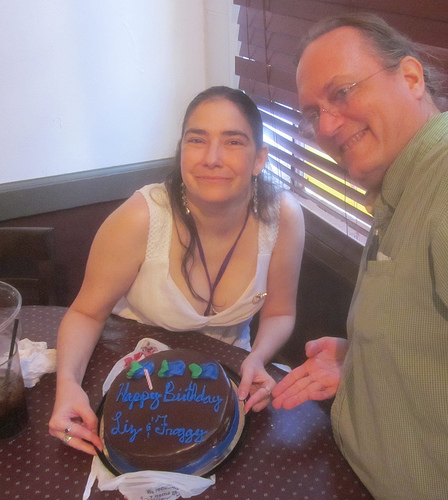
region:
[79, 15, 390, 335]
a mom and dad giving a birthday cake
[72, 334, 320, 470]
a brown and blue birthday cake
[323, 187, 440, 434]
the man has on a green shirt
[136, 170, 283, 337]
this lady is wearing a white shirt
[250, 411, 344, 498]
a brown table cloth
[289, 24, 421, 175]
this man is wearing glasses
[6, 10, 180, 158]
this wall in the house is white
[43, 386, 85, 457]
rings on the woman's fingers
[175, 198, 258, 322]
a badge string around the lady's neck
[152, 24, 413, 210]
the couple is happy about the cake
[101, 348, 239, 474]
a chocolate birthday cake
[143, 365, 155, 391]
one white birthday candle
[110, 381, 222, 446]
writing with blue frosting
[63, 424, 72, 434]
a ring on her right finger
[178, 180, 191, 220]
long gold color earing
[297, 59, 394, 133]
wire rim eye glasses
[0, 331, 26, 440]
a clear glass of soda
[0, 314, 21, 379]
a plastic drink stirrer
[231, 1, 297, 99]
brown horizontal blinds on the window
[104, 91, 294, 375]
this is a lady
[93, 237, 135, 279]
the lady is light skinned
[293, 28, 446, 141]
this is a man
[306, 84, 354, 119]
this is a spectacle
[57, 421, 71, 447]
this is a ring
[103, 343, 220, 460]
this is a cake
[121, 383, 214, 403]
this is a writing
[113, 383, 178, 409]
the writing is in blue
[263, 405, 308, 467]
this is a table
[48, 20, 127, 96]
this is a wall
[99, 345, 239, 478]
chocolate birthday cake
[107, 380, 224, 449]
blue frosting on chocolate birthday cake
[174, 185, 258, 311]
woman wearing purple necklace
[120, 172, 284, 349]
woman wearing white tank top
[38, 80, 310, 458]
woman presenting birthday cake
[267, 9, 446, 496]
man presenting birthday cake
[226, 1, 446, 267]
brown shutters on window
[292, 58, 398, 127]
man wearing glasses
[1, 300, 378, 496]
brown table top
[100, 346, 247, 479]
chocolate cake decorated with blue and green frosting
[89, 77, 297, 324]
this is a lady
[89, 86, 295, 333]
the lady is sitted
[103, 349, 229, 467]
this is a cake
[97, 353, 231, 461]
the cake is brown in color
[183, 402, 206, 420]
the cake is brown in color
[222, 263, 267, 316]
this is the boob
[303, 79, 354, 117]
this is a spectacles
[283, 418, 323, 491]
this is a table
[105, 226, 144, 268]
the lady is light skinned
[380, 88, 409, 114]
the man is light skinned